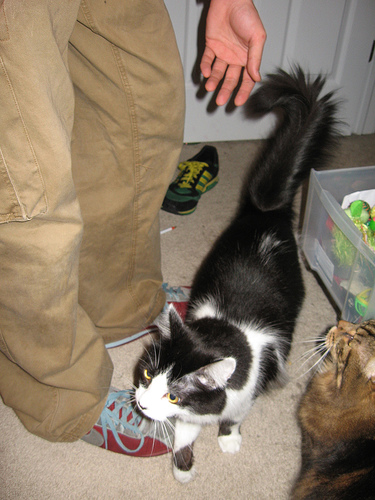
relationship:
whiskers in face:
[134, 336, 184, 459] [115, 294, 243, 430]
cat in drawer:
[137, 67, 350, 484] [301, 162, 373, 327]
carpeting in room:
[2, 131, 373, 498] [2, 0, 373, 498]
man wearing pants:
[0, 0, 266, 456] [2, 6, 191, 424]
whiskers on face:
[135, 426, 207, 478] [100, 333, 232, 434]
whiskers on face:
[99, 363, 149, 421] [100, 333, 232, 434]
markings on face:
[123, 360, 193, 431] [125, 303, 239, 427]